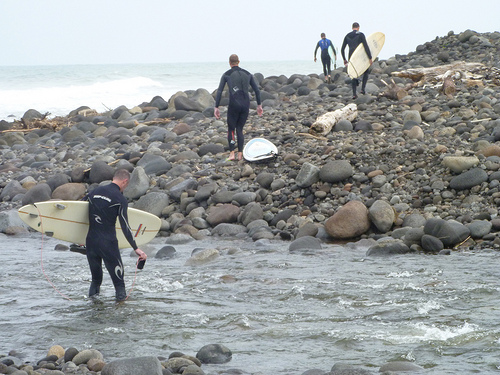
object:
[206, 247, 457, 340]
water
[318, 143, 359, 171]
stone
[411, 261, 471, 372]
splash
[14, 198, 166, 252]
board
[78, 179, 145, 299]
costume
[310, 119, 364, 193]
rock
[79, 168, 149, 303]
man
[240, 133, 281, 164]
board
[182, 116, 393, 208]
ground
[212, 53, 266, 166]
man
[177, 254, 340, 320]
waves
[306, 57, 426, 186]
up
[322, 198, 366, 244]
rocks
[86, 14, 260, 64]
sky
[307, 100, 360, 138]
log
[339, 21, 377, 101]
people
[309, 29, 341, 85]
surfers